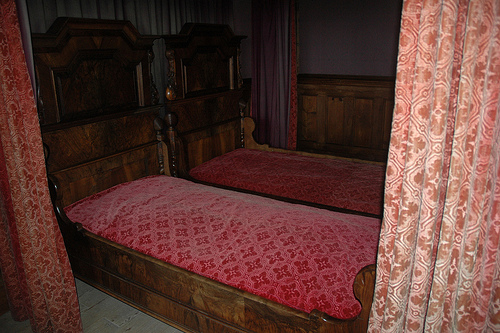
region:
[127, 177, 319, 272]
this is a bed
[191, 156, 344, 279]
the beds are two in number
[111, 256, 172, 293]
the bed is wooden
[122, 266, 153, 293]
the bed is brown in color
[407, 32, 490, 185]
this is a curtain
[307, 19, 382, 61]
this is the wall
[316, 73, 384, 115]
this is a cupboard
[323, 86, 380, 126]
the cupboard is wooden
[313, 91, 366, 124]
the cupboard is brown in color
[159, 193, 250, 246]
this is the mattress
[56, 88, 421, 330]
a couple of red beds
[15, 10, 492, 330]
a scene in a bedroom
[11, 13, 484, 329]
a scene inside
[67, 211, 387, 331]
a wooden bed frame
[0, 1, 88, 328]
a curtain on the left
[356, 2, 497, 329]
a curtain on the right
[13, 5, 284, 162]
white curtain behind the beds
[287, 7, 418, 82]
a white wall in the back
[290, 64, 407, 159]
a wooden panel on the south wall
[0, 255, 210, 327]
a white tile floor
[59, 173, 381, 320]
red fabric on a bed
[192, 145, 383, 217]
red fabric on a bed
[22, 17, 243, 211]
wooden headboards on beds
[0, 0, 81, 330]
red ornate hanging fabric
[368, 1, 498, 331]
red ornate hanging fabric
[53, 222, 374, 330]
wood on the side of a bed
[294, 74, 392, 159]
wooden paneling on the wall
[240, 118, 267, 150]
wood paneling on a bed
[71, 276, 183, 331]
tiles on the floor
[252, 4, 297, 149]
ornate hanging fabric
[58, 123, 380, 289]
two beds on the ground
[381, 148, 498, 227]
curtain next to the bed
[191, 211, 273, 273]
red mattress with patterns on it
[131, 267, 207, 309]
wooden bed frame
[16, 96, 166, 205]
headboard of the bed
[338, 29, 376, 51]
wall in the room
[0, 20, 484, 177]
two curtains in the room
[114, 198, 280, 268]
mattress with no blanket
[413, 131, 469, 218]
design on the curtain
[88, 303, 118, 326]
floor next to bed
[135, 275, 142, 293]
edge of a bed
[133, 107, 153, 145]
top of a bed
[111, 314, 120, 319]
part of the floor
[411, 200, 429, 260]
part of a curtain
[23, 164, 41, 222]
edge of a curtain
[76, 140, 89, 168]
top of the bed